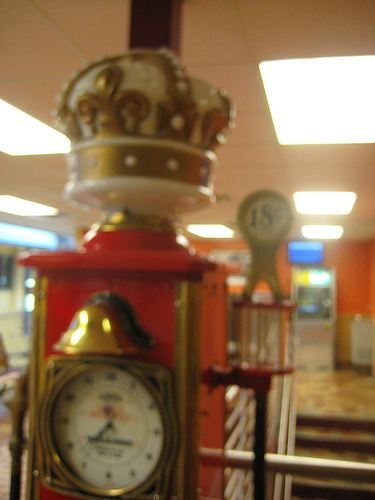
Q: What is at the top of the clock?
A: A crown.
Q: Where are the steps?
A: In the lower right corner.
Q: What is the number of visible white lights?
A: Six.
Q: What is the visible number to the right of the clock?
A: 18.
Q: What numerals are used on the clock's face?
A: Arabic.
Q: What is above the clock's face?
A: A metal bell.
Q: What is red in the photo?
A: The light.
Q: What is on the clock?
A: A crown.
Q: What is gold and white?
A: The crown.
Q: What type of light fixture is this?
A: Florescent.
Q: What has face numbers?
A: The clock.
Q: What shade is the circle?
A: Gold.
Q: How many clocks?
A: One.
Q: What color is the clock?
A: Red.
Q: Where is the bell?
A: Above the clock.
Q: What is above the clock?
A: Crown.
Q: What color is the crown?
A: Gold and white.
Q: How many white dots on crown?
A: Five.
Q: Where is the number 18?
A: The pole behind the clock.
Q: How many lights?
A: Six.